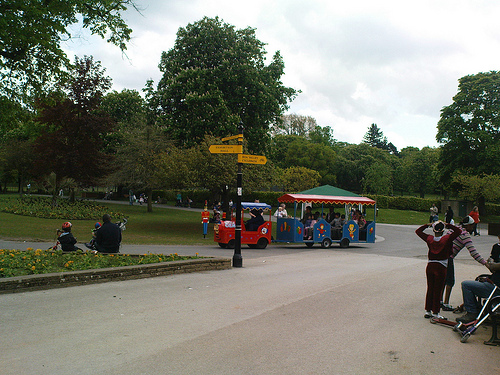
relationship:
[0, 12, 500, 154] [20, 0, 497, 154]
cloud hanging in sky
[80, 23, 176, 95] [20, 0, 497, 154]
cloud hanging in sky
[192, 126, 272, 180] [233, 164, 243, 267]
signs on black pole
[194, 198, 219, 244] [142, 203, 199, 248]
soldier on grass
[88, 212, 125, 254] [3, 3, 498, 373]
person in park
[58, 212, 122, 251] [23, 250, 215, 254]
people on curb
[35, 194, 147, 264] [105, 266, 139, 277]
people sitting down brick.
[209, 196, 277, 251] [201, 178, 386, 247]
train engine on a train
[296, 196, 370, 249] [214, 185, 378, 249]
people are in a train